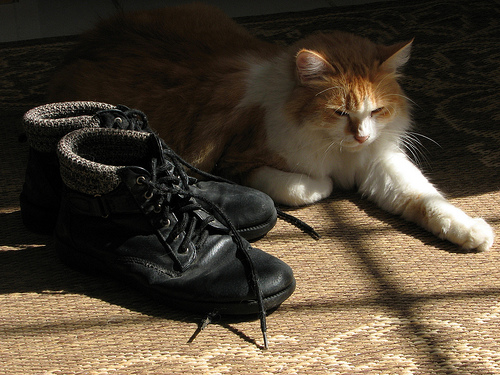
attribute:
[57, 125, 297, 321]
shoe — black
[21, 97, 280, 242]
shoe — black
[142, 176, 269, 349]
laces — untied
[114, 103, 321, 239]
laces — untied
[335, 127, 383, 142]
nose — pink, little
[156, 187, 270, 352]
shoe lace — black, untied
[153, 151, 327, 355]
laces — on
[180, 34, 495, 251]
cat — long hair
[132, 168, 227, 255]
laces — untied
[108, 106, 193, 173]
laces — untied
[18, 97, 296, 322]
shoe — black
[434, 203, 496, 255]
paw — cat, outstretched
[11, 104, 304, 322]
shoes — black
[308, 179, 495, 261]
paws — on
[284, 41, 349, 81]
ear — pointy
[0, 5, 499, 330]
shadow — on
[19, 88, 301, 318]
boot — untied, black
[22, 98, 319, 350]
booties — black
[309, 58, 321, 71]
hair — ear, white, long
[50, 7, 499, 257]
cat — white, tan, tired